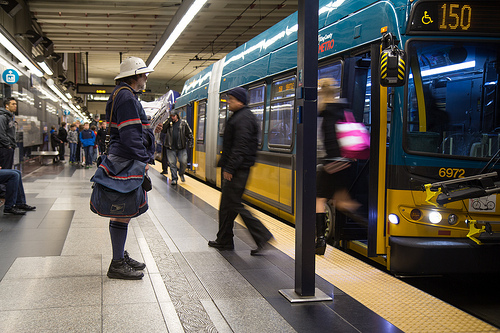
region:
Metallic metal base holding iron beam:
[280, 285, 327, 300]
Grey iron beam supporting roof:
[295, 222, 316, 293]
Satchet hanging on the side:
[90, 193, 140, 216]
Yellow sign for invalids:
[420, 10, 432, 24]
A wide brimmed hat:
[113, 60, 149, 75]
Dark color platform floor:
[296, 304, 323, 329]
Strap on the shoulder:
[112, 93, 115, 102]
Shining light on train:
[428, 210, 442, 224]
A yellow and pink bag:
[337, 122, 371, 155]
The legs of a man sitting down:
[1, 166, 33, 214]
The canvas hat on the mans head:
[108, 43, 155, 81]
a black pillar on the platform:
[294, 0, 321, 300]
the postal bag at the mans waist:
[91, 159, 153, 218]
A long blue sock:
[106, 221, 131, 261]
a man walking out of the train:
[201, 67, 272, 263]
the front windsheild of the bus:
[405, 35, 495, 155]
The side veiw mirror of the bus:
[380, 40, 400, 80]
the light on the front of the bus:
[385, 205, 461, 231]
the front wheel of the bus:
[325, 198, 340, 244]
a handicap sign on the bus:
[417, 6, 434, 30]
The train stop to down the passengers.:
[156, 2, 499, 279]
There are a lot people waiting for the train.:
[48, 55, 193, 284]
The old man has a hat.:
[88, 55, 153, 281]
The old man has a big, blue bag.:
[90, 55, 147, 277]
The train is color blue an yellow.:
[175, 21, 495, 267]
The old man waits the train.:
[91, 51, 151, 276]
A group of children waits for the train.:
[61, 120, 106, 165]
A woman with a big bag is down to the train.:
[315, 75, 370, 255]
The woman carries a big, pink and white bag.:
[333, 110, 372, 154]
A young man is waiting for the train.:
[1, 94, 21, 170]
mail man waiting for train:
[96, 44, 173, 282]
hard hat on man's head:
[117, 49, 154, 81]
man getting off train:
[220, 80, 274, 268]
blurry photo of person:
[316, 68, 359, 232]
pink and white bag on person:
[334, 98, 368, 158]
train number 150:
[442, 3, 478, 40]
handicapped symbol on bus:
[421, 8, 446, 26]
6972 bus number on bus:
[435, 165, 464, 180]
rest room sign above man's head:
[4, 63, 21, 86]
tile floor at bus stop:
[20, 244, 110, 321]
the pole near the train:
[294, 0, 318, 299]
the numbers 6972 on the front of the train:
[437, 166, 466, 178]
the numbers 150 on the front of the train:
[438, 3, 470, 31]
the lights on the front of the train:
[386, 204, 441, 227]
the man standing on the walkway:
[89, 55, 155, 280]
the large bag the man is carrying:
[88, 155, 148, 217]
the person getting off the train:
[313, 75, 368, 254]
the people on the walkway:
[0, 54, 370, 280]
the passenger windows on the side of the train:
[161, 58, 342, 163]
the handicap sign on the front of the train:
[421, 9, 433, 25]